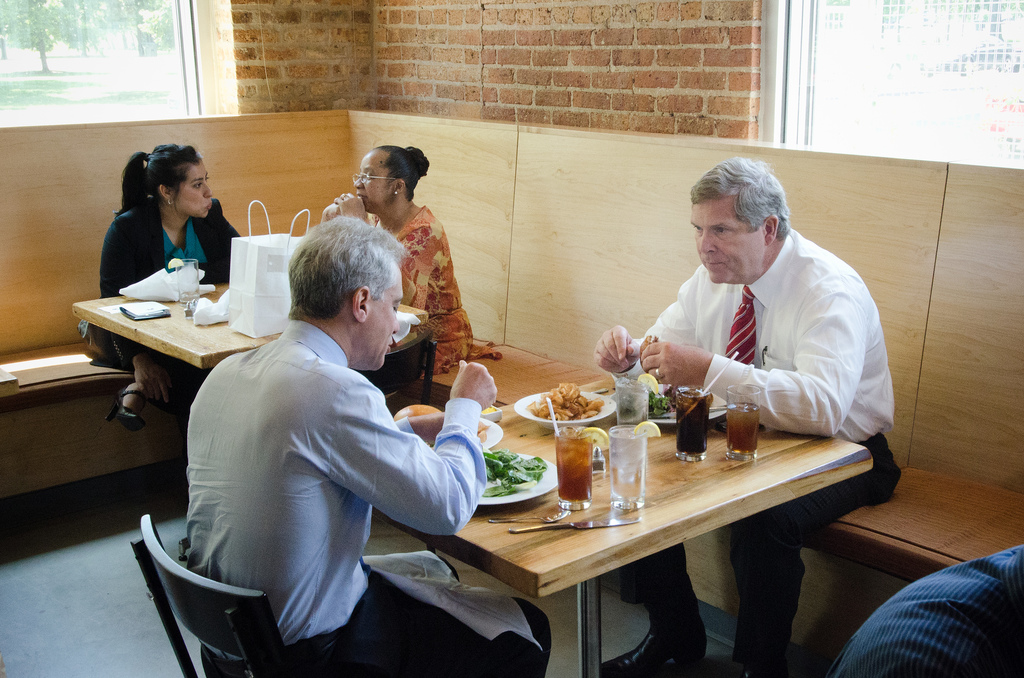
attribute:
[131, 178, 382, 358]
bag — white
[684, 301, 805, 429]
tie — red, white, striped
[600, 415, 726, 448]
lemon — sliced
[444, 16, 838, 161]
wall — red, brick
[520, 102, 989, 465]
bench — wood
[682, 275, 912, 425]
shirt — white, dress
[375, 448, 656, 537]
plate — dark green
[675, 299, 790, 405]
necktie — red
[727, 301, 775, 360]
stripes — diagonal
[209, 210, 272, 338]
shopping bag — white, paper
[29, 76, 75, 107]
lawn — green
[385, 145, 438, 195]
bun — tight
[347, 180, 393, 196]
glasses — metal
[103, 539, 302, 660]
chair — black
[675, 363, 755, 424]
straw — white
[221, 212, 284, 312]
bag — white, paper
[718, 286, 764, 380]
tie — red, white, striped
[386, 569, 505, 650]
napkin — white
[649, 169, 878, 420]
man — black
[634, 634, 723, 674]
shoes — shiny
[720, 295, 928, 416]
shirt — white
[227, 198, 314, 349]
bag — white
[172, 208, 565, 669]
men — eating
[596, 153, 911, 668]
men — eating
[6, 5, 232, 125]
window — glass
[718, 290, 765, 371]
tie — red, striped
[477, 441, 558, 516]
plate — white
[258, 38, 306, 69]
brick — red 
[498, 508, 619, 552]
knife — silver